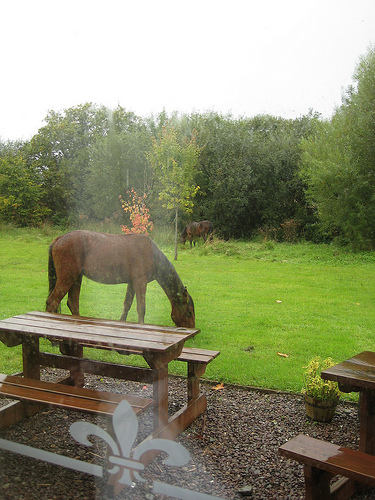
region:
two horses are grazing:
[30, 186, 237, 335]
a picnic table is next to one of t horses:
[2, 280, 214, 445]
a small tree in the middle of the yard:
[143, 113, 205, 272]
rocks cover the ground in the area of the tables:
[3, 365, 346, 498]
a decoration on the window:
[67, 377, 193, 490]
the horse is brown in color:
[38, 220, 197, 335]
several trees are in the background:
[10, 52, 367, 240]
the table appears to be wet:
[1, 308, 189, 375]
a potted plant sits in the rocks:
[293, 348, 340, 421]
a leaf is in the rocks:
[209, 376, 227, 393]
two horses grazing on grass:
[43, 210, 216, 333]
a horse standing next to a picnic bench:
[6, 232, 195, 431]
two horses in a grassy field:
[44, 217, 219, 334]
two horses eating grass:
[43, 214, 215, 328]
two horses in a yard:
[45, 219, 208, 325]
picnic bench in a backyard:
[287, 351, 372, 496]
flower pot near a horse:
[297, 354, 338, 423]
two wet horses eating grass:
[46, 215, 216, 330]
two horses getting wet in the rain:
[49, 222, 219, 329]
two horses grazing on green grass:
[46, 218, 212, 328]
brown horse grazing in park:
[40, 223, 205, 348]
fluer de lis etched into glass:
[1, 394, 215, 494]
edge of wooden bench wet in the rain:
[274, 345, 370, 487]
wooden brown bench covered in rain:
[2, 297, 217, 447]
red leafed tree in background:
[116, 185, 158, 235]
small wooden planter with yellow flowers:
[300, 354, 342, 422]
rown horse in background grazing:
[180, 214, 220, 252]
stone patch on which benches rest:
[0, 353, 371, 489]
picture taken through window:
[0, 0, 372, 495]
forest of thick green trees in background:
[0, 42, 373, 254]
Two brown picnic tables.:
[2, 306, 374, 494]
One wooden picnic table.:
[278, 350, 373, 494]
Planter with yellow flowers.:
[293, 355, 343, 423]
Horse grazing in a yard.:
[42, 228, 198, 337]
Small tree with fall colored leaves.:
[116, 186, 153, 239]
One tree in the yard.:
[148, 124, 204, 261]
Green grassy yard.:
[1, 227, 370, 389]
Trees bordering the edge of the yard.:
[4, 43, 368, 243]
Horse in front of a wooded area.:
[179, 219, 216, 252]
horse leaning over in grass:
[31, 224, 207, 334]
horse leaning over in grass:
[172, 206, 219, 245]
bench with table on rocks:
[2, 300, 214, 468]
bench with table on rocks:
[288, 332, 366, 484]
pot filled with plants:
[295, 341, 344, 419]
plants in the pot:
[300, 353, 338, 399]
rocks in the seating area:
[20, 375, 291, 498]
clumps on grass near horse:
[204, 235, 294, 257]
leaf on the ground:
[209, 377, 235, 405]